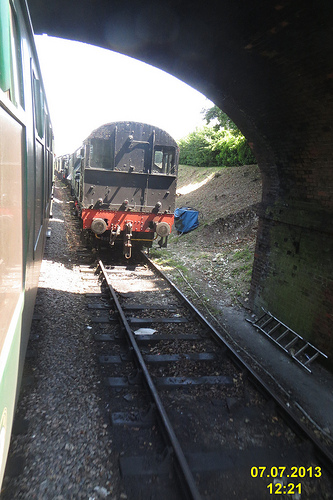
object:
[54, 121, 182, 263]
train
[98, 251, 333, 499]
tracks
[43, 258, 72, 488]
rocks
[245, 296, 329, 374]
ladder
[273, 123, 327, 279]
wall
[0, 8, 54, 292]
fence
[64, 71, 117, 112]
sky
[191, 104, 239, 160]
bush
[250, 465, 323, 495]
text